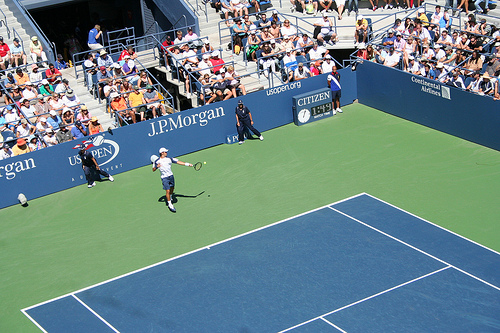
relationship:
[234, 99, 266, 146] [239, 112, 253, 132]
ball boy wearing clothes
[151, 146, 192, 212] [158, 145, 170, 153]
man wearing hat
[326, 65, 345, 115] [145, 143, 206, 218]
man wearing shirt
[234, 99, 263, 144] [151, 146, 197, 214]
ball boy behind man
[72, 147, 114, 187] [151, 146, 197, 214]
ball boy behind man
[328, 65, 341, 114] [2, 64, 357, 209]
man leaning against partition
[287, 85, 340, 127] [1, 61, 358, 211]
clock on wall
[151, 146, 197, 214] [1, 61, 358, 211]
man standing near wall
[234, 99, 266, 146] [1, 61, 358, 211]
ball boy standing near wall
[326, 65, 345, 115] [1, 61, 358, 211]
man standing near wall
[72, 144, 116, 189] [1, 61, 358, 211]
ball boy standing near wall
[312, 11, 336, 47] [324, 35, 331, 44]
person sitting in chair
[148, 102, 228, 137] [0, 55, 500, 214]
advertisement on partition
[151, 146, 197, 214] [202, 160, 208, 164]
man hitting ball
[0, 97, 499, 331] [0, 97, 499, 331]
court on court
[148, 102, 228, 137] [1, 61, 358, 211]
advertisement on wall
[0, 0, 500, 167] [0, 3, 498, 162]
spectator in bleachers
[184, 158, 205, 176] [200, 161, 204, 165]
tennis raquet hitting ball